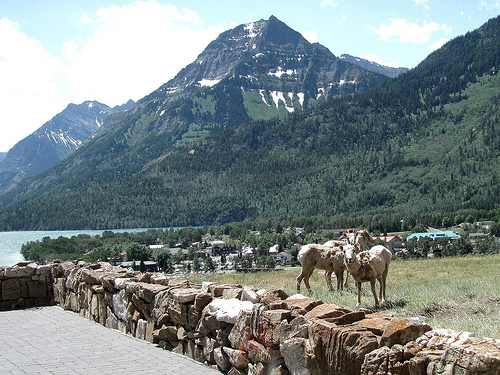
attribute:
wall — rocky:
[159, 289, 254, 358]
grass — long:
[423, 261, 496, 293]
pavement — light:
[12, 324, 60, 371]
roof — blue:
[405, 230, 459, 242]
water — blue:
[3, 218, 206, 270]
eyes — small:
[341, 243, 358, 257]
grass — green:
[439, 270, 469, 290]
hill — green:
[297, 110, 338, 169]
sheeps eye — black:
[351, 249, 359, 255]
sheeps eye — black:
[341, 247, 348, 253]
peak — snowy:
[208, 3, 324, 71]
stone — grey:
[104, 307, 119, 327]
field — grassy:
[147, 252, 497, 350]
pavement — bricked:
[0, 305, 228, 372]